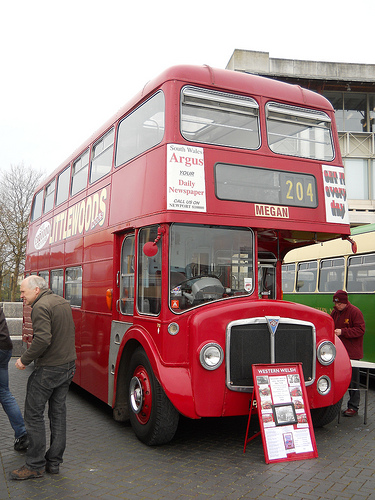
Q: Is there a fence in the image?
A: No, there are no fences.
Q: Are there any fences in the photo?
A: No, there are no fences.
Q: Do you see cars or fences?
A: No, there are no fences or cars.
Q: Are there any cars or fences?
A: No, there are no fences or cars.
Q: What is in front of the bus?
A: The sign is in front of the bus.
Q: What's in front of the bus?
A: The sign is in front of the bus.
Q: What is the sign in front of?
A: The sign is in front of the bus.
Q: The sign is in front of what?
A: The sign is in front of the bus.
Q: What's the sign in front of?
A: The sign is in front of the bus.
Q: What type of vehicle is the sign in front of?
A: The sign is in front of the bus.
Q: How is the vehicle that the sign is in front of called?
A: The vehicle is a bus.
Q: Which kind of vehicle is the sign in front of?
A: The sign is in front of the bus.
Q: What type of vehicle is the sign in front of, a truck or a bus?
A: The sign is in front of a bus.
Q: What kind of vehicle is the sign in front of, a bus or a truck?
A: The sign is in front of a bus.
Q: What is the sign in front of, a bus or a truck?
A: The sign is in front of a bus.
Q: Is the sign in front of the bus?
A: Yes, the sign is in front of the bus.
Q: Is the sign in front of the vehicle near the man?
A: Yes, the sign is in front of the bus.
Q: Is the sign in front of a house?
A: No, the sign is in front of the bus.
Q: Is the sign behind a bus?
A: No, the sign is in front of a bus.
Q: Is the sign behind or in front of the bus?
A: The sign is in front of the bus.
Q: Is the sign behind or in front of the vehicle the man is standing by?
A: The sign is in front of the bus.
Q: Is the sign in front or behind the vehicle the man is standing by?
A: The sign is in front of the bus.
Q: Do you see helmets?
A: No, there are no helmets.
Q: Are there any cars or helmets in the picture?
A: No, there are no helmets or cars.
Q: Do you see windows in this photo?
A: Yes, there is a window.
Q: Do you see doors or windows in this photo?
A: Yes, there is a window.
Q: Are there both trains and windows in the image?
A: No, there is a window but no trains.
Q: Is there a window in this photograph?
A: Yes, there is a window.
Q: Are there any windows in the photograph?
A: Yes, there is a window.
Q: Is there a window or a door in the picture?
A: Yes, there is a window.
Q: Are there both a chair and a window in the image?
A: No, there is a window but no chairs.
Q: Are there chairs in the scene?
A: No, there are no chairs.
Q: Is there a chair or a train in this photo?
A: No, there are no chairs or trains.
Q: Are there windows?
A: Yes, there is a window.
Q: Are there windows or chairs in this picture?
A: Yes, there is a window.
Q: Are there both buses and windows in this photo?
A: Yes, there are both a window and a bus.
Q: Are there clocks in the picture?
A: No, there are no clocks.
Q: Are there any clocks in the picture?
A: No, there are no clocks.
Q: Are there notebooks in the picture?
A: No, there are no notebooks.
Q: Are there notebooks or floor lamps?
A: No, there are no notebooks or floor lamps.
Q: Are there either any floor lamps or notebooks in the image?
A: No, there are no notebooks or floor lamps.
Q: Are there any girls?
A: No, there are no girls.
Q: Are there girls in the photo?
A: No, there are no girls.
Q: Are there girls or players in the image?
A: No, there are no girls or players.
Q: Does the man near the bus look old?
A: Yes, the man is old.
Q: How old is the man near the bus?
A: The man is old.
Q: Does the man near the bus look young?
A: No, the man is old.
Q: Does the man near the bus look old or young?
A: The man is old.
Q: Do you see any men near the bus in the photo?
A: Yes, there is a man near the bus.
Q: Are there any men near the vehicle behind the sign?
A: Yes, there is a man near the bus.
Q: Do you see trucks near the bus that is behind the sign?
A: No, there is a man near the bus.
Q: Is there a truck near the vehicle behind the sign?
A: No, there is a man near the bus.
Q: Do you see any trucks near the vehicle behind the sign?
A: No, there is a man near the bus.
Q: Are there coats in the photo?
A: Yes, there is a coat.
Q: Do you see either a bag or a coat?
A: Yes, there is a coat.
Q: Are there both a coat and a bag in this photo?
A: No, there is a coat but no bags.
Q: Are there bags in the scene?
A: No, there are no bags.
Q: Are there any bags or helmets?
A: No, there are no bags or helmets.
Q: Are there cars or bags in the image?
A: No, there are no cars or bags.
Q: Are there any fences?
A: No, there are no fences.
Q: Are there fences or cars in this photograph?
A: No, there are no fences or cars.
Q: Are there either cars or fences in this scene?
A: No, there are no fences or cars.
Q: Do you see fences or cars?
A: No, there are no fences or cars.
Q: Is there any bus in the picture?
A: Yes, there is a bus.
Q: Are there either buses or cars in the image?
A: Yes, there is a bus.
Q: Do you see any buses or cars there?
A: Yes, there is a bus.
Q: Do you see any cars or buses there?
A: Yes, there is a bus.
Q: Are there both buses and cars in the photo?
A: No, there is a bus but no cars.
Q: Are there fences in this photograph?
A: No, there are no fences.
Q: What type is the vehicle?
A: The vehicle is a bus.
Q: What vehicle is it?
A: The vehicle is a bus.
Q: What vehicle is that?
A: That is a bus.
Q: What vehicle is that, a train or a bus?
A: That is a bus.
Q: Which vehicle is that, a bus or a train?
A: That is a bus.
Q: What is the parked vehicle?
A: The vehicle is a bus.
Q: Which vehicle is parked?
A: The vehicle is a bus.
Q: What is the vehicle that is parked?
A: The vehicle is a bus.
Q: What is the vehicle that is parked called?
A: The vehicle is a bus.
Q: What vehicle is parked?
A: The vehicle is a bus.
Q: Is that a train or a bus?
A: That is a bus.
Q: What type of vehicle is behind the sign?
A: The vehicle is a bus.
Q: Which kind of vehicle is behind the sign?
A: The vehicle is a bus.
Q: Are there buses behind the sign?
A: Yes, there is a bus behind the sign.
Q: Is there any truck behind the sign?
A: No, there is a bus behind the sign.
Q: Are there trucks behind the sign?
A: No, there is a bus behind the sign.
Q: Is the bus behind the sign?
A: Yes, the bus is behind the sign.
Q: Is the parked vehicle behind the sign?
A: Yes, the bus is behind the sign.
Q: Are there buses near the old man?
A: Yes, there is a bus near the man.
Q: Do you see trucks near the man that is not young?
A: No, there is a bus near the man.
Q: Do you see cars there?
A: No, there are no cars.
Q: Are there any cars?
A: No, there are no cars.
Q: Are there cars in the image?
A: No, there are no cars.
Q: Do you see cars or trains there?
A: No, there are no cars or trains.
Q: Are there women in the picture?
A: No, there are no women.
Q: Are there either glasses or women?
A: No, there are no women or glasses.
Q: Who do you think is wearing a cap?
A: The man is wearing a cap.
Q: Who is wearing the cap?
A: The man is wearing a cap.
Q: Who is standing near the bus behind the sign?
A: The man is standing near the bus.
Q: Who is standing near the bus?
A: The man is standing near the bus.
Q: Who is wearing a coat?
A: The man is wearing a coat.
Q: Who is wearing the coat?
A: The man is wearing a coat.